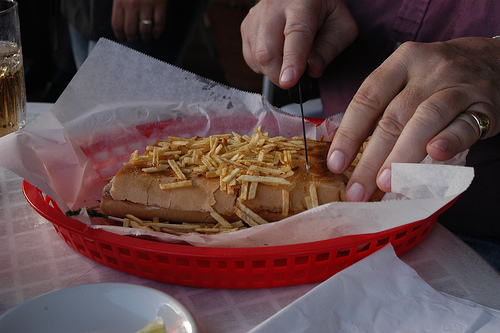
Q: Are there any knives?
A: Yes, there is a knife.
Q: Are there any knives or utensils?
A: Yes, there is a knife.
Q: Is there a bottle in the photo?
A: No, there are no bottles.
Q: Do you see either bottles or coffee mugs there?
A: No, there are no bottles or coffee mugs.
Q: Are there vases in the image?
A: No, there are no vases.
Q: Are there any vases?
A: No, there are no vases.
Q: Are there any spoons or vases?
A: No, there are no vases or spoons.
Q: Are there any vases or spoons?
A: No, there are no vases or spoons.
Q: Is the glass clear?
A: Yes, the glass is clear.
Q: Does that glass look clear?
A: Yes, the glass is clear.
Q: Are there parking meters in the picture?
A: No, there are no parking meters.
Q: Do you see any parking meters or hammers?
A: No, there are no parking meters or hammers.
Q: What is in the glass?
A: The liquid is in the glass.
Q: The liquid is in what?
A: The liquid is in the glass.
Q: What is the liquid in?
A: The liquid is in the glass.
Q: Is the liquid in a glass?
A: Yes, the liquid is in a glass.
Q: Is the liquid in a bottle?
A: No, the liquid is in a glass.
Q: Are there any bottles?
A: No, there are no bottles.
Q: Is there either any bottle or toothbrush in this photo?
A: No, there are no bottles or toothbrushes.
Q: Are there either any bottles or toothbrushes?
A: No, there are no bottles or toothbrushes.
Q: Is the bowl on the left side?
A: Yes, the bowl is on the left of the image.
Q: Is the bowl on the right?
A: No, the bowl is on the left of the image.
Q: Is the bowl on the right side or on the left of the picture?
A: The bowl is on the left of the image.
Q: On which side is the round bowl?
A: The bowl is on the left of the image.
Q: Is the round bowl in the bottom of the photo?
A: Yes, the bowl is in the bottom of the image.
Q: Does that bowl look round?
A: Yes, the bowl is round.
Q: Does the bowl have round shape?
A: Yes, the bowl is round.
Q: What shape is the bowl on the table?
A: The bowl is round.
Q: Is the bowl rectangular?
A: No, the bowl is round.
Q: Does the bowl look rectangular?
A: No, the bowl is round.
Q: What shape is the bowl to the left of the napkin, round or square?
A: The bowl is round.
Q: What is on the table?
A: The bowl is on the table.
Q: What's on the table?
A: The bowl is on the table.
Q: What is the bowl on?
A: The bowl is on the table.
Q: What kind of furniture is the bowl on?
A: The bowl is on the table.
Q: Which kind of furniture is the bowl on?
A: The bowl is on the table.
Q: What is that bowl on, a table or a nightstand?
A: The bowl is on a table.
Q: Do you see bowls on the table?
A: Yes, there is a bowl on the table.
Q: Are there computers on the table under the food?
A: No, there is a bowl on the table.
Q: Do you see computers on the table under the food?
A: No, there is a bowl on the table.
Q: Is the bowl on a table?
A: Yes, the bowl is on a table.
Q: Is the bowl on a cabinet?
A: No, the bowl is on a table.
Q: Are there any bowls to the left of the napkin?
A: Yes, there is a bowl to the left of the napkin.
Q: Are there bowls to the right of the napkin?
A: No, the bowl is to the left of the napkin.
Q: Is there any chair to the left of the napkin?
A: No, there is a bowl to the left of the napkin.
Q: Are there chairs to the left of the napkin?
A: No, there is a bowl to the left of the napkin.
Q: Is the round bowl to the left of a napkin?
A: Yes, the bowl is to the left of a napkin.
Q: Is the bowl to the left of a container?
A: No, the bowl is to the left of a napkin.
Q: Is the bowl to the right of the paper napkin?
A: No, the bowl is to the left of the napkin.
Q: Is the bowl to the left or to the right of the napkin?
A: The bowl is to the left of the napkin.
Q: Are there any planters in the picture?
A: No, there are no planters.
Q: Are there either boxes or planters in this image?
A: No, there are no planters or boxes.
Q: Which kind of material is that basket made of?
A: The basket is made of plastic.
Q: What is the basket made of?
A: The basket is made of plastic.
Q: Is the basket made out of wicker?
A: No, the basket is made of plastic.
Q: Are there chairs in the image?
A: No, there are no chairs.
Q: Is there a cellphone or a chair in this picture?
A: No, there are no chairs or cell phones.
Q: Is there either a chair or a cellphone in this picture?
A: No, there are no chairs or cell phones.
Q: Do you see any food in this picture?
A: Yes, there is food.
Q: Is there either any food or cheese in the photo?
A: Yes, there is food.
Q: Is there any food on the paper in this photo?
A: Yes, there is food on the paper.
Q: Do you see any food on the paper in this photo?
A: Yes, there is food on the paper.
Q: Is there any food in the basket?
A: Yes, there is food in the basket.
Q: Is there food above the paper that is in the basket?
A: Yes, there is food above the paper.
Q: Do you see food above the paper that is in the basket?
A: Yes, there is food above the paper.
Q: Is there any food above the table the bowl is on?
A: Yes, there is food above the table.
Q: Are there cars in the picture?
A: No, there are no cars.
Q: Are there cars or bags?
A: No, there are no cars or bags.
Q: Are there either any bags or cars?
A: No, there are no cars or bags.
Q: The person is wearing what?
A: The person is wearing a ring.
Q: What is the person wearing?
A: The person is wearing a ring.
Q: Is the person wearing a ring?
A: Yes, the person is wearing a ring.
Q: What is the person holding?
A: The person is holding the knife.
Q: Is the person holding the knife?
A: Yes, the person is holding the knife.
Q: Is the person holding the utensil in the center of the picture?
A: Yes, the person is holding the knife.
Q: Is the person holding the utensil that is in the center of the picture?
A: Yes, the person is holding the knife.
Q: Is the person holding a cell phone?
A: No, the person is holding the knife.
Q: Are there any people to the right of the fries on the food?
A: Yes, there is a person to the right of the French fries.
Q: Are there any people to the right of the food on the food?
A: Yes, there is a person to the right of the French fries.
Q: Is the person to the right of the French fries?
A: Yes, the person is to the right of the French fries.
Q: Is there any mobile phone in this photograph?
A: No, there are no cell phones.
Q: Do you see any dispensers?
A: No, there are no dispensers.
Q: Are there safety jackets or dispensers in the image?
A: No, there are no dispensers or safety jackets.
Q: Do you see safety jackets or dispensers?
A: No, there are no dispensers or safety jackets.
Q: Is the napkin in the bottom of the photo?
A: Yes, the napkin is in the bottom of the image.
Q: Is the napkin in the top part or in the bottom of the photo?
A: The napkin is in the bottom of the image.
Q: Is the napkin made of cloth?
A: No, the napkin is made of paper.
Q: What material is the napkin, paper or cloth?
A: The napkin is made of paper.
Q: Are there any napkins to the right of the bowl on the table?
A: Yes, there is a napkin to the right of the bowl.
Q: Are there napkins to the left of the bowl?
A: No, the napkin is to the right of the bowl.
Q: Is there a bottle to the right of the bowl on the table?
A: No, there is a napkin to the right of the bowl.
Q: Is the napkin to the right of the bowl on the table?
A: Yes, the napkin is to the right of the bowl.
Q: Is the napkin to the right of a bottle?
A: No, the napkin is to the right of the bowl.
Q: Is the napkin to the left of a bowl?
A: No, the napkin is to the right of a bowl.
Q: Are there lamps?
A: No, there are no lamps.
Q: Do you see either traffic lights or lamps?
A: No, there are no lamps or traffic lights.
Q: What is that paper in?
A: The paper is in the basket.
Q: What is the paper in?
A: The paper is in the basket.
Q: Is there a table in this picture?
A: Yes, there is a table.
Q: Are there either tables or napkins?
A: Yes, there is a table.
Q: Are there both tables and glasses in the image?
A: Yes, there are both a table and glasses.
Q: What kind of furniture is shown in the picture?
A: The furniture is a table.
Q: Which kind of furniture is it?
A: The piece of furniture is a table.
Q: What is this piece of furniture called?
A: This is a table.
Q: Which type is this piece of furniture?
A: This is a table.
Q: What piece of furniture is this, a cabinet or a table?
A: This is a table.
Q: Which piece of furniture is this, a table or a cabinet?
A: This is a table.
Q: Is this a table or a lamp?
A: This is a table.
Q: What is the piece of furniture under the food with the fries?
A: The piece of furniture is a table.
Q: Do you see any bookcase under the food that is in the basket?
A: No, there is a table under the food.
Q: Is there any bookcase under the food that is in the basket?
A: No, there is a table under the food.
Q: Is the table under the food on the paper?
A: Yes, the table is under the food.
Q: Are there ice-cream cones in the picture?
A: No, there are no ice-cream cones.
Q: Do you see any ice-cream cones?
A: No, there are no ice-cream cones.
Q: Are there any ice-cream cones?
A: No, there are no ice-cream cones.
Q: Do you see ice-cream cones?
A: No, there are no ice-cream cones.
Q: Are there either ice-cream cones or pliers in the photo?
A: No, there are no ice-cream cones or pliers.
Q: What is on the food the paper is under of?
A: The French fries are on the food.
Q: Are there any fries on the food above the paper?
A: Yes, there are fries on the food.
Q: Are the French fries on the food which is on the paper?
A: Yes, the French fries are on the food.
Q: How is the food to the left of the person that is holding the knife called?
A: The food is fries.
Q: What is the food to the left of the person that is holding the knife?
A: The food is fries.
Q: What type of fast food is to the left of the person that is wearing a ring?
A: The food is fries.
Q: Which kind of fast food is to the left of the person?
A: The food is fries.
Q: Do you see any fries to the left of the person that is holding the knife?
A: Yes, there are fries to the left of the person.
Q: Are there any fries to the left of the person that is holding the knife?
A: Yes, there are fries to the left of the person.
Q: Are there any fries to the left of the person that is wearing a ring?
A: Yes, there are fries to the left of the person.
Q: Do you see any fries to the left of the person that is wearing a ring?
A: Yes, there are fries to the left of the person.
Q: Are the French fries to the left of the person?
A: Yes, the French fries are to the left of the person.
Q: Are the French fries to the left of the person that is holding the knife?
A: Yes, the French fries are to the left of the person.